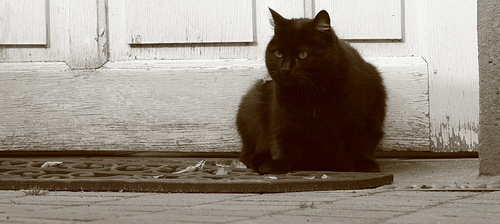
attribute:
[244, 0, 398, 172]
cat — black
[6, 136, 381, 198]
placemat — black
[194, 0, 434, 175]
cat — black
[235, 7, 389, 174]
cat — black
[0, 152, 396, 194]
doormat — black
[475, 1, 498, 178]
wall — cement